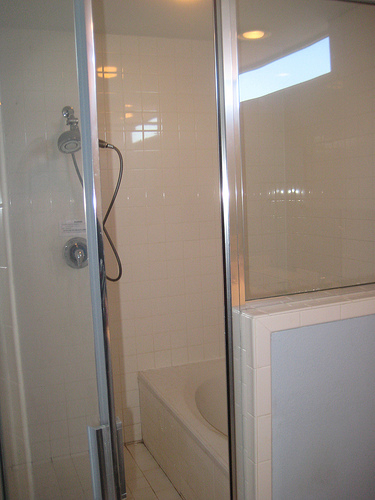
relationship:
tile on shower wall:
[171, 328, 189, 347] [146, 172, 224, 282]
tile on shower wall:
[152, 349, 172, 368] [3, 29, 243, 459]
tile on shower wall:
[140, 166, 185, 214] [130, 43, 218, 339]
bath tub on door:
[137, 357, 254, 499] [0, 0, 126, 500]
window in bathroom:
[218, 33, 353, 91] [20, 17, 373, 480]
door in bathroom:
[6, 0, 128, 492] [1, 0, 372, 498]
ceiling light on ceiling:
[242, 30, 265, 39] [0, 1, 363, 39]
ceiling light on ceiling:
[231, 17, 277, 56] [2, 0, 361, 42]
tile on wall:
[237, 311, 272, 466] [238, 285, 374, 499]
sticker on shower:
[62, 218, 87, 232] [5, 21, 371, 496]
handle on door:
[85, 424, 121, 499] [6, 0, 128, 492]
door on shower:
[6, 0, 128, 492] [5, 21, 371, 496]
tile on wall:
[130, 51, 225, 254] [123, 39, 215, 360]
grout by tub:
[137, 439, 145, 447] [134, 356, 239, 498]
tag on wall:
[57, 217, 88, 238] [16, 16, 54, 324]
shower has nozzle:
[0, 0, 231, 497] [54, 106, 118, 157]